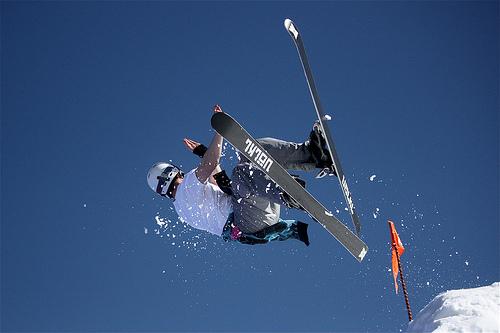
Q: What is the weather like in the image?
A: It is clear.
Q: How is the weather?
A: It is clear.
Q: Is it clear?
A: Yes, it is clear.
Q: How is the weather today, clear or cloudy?
A: It is clear.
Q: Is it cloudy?
A: No, it is clear.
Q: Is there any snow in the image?
A: Yes, there is snow.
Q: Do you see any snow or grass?
A: Yes, there is snow.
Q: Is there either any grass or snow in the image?
A: Yes, there is snow.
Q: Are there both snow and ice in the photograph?
A: No, there is snow but no ice.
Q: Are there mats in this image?
A: No, there are no mats.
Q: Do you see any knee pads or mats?
A: No, there are no mats or knee pads.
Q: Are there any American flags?
A: No, there are no American flags.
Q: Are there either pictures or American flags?
A: No, there are no American flags or pictures.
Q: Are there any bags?
A: No, there are no bags.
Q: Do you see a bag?
A: No, there are no bags.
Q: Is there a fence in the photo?
A: No, there are no fences.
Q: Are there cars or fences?
A: No, there are no fences or cars.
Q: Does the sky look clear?
A: Yes, the sky is clear.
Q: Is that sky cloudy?
A: No, the sky is clear.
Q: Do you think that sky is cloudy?
A: No, the sky is clear.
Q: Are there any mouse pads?
A: No, there are no mouse pads.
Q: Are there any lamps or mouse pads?
A: No, there are no mouse pads or lamps.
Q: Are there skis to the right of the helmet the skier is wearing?
A: Yes, there is a ski to the right of the helmet.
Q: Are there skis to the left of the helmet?
A: No, the ski is to the right of the helmet.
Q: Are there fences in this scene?
A: No, there are no fences.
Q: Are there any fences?
A: No, there are no fences.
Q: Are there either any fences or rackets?
A: No, there are no fences or rackets.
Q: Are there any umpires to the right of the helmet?
A: No, there is a ski to the right of the helmet.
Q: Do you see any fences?
A: No, there are no fences.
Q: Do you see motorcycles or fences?
A: No, there are no fences or motorcycles.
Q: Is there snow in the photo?
A: Yes, there is snow.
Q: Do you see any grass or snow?
A: Yes, there is snow.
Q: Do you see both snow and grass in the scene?
A: No, there is snow but no grass.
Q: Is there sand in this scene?
A: No, there is no sand.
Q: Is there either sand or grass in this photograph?
A: No, there are no sand or grass.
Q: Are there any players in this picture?
A: No, there are no players.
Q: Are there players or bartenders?
A: No, there are no players or bartenders.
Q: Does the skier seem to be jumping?
A: Yes, the skier is jumping.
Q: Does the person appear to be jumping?
A: Yes, the skier is jumping.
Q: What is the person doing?
A: The skier is jumping.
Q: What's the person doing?
A: The skier is jumping.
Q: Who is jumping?
A: The skier is jumping.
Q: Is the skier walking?
A: No, the skier is jumping.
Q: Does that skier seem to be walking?
A: No, the skier is jumping.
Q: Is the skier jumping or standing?
A: The skier is jumping.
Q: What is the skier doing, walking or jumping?
A: The skier is jumping.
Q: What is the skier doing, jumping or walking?
A: The skier is jumping.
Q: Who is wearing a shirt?
A: The skier is wearing a shirt.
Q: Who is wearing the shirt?
A: The skier is wearing a shirt.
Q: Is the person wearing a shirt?
A: Yes, the skier is wearing a shirt.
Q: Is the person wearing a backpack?
A: No, the skier is wearing a shirt.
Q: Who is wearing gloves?
A: The skier is wearing gloves.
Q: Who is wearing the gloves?
A: The skier is wearing gloves.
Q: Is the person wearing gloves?
A: Yes, the skier is wearing gloves.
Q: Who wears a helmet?
A: The skier wears a helmet.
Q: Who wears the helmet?
A: The skier wears a helmet.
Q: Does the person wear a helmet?
A: Yes, the skier wears a helmet.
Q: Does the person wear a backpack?
A: No, the skier wears a helmet.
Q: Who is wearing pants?
A: The skier is wearing pants.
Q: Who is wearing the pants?
A: The skier is wearing pants.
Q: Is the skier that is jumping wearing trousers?
A: Yes, the skier is wearing trousers.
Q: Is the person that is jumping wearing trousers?
A: Yes, the skier is wearing trousers.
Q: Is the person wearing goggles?
A: No, the skier is wearing trousers.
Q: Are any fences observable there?
A: No, there are no fences.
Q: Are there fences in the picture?
A: No, there are no fences.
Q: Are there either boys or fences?
A: No, there are no fences or boys.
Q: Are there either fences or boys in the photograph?
A: No, there are no fences or boys.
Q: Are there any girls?
A: No, there are no girls.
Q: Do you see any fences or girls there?
A: No, there are no girls or fences.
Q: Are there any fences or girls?
A: No, there are no girls or fences.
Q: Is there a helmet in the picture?
A: Yes, there is a helmet.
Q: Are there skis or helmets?
A: Yes, there is a helmet.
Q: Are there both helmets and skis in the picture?
A: Yes, there are both a helmet and skis.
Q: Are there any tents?
A: No, there are no tents.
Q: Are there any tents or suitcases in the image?
A: No, there are no tents or suitcases.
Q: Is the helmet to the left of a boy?
A: No, the helmet is to the left of a ski.